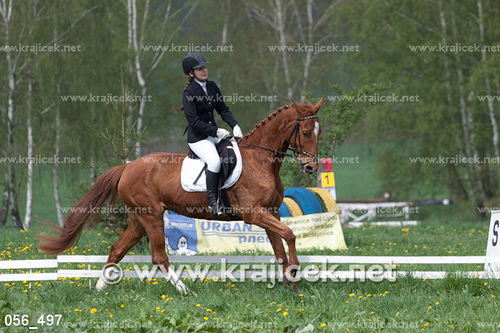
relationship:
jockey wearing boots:
[177, 49, 247, 218] [197, 137, 247, 221]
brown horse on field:
[36, 95, 324, 297] [18, 207, 497, 327]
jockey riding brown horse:
[177, 49, 247, 218] [36, 95, 324, 297]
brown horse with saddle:
[36, 95, 324, 297] [179, 119, 253, 206]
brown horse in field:
[36, 95, 324, 297] [3, 225, 499, 330]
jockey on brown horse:
[177, 49, 247, 218] [36, 95, 324, 297]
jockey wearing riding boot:
[177, 49, 247, 218] [205, 168, 224, 212]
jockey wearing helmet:
[177, 49, 247, 218] [180, 53, 209, 75]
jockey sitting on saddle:
[177, 49, 247, 218] [183, 125, 288, 181]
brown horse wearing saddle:
[36, 95, 324, 297] [178, 138, 249, 193]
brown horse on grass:
[36, 95, 324, 297] [3, 213, 493, 332]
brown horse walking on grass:
[36, 95, 324, 297] [3, 213, 493, 332]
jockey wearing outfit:
[177, 49, 247, 218] [181, 75, 247, 198]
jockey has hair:
[177, 49, 247, 218] [182, 67, 194, 93]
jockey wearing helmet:
[177, 49, 247, 218] [177, 50, 215, 76]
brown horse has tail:
[36, 95, 324, 297] [31, 166, 125, 261]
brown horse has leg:
[36, 95, 324, 297] [261, 214, 286, 278]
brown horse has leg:
[36, 95, 324, 297] [244, 210, 298, 292]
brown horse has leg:
[36, 95, 324, 297] [137, 213, 189, 293]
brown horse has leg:
[36, 95, 324, 297] [95, 210, 143, 291]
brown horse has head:
[36, 95, 324, 297] [288, 93, 328, 176]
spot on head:
[307, 109, 320, 140] [288, 93, 328, 176]